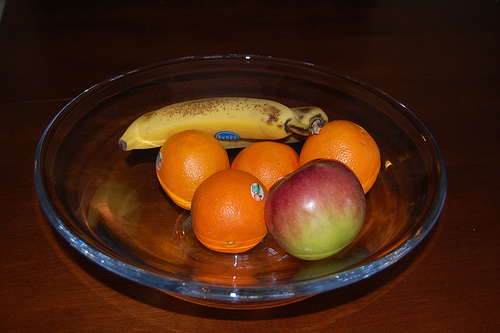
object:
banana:
[118, 97, 322, 151]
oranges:
[190, 169, 268, 253]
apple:
[263, 159, 366, 261]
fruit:
[118, 97, 380, 261]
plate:
[29, 53, 448, 303]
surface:
[0, 2, 494, 333]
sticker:
[215, 131, 242, 140]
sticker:
[250, 183, 264, 202]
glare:
[303, 199, 317, 213]